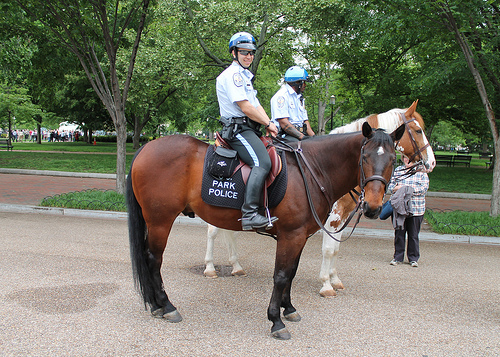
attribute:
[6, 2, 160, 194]
tree — green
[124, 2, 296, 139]
tree — green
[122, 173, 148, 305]
tail — long, black